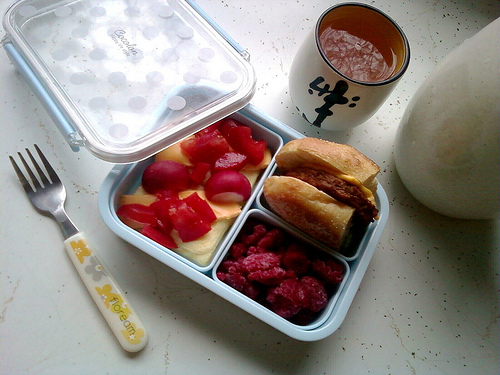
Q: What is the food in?
A: A bento box.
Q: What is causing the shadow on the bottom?
A: Bento box.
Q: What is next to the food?
A: A fork.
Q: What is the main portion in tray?
A: Vegetables.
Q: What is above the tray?
A: Cup of drink.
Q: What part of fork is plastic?
A: Bottom.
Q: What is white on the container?
A: A lid.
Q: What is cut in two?
A: The bread.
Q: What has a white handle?
A: The fork.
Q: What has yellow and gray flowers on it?
A: Fork handle.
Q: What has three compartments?
A: Food container.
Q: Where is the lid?
A: On top of the food container.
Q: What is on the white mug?
A: An asian character.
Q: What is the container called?
A: Bento box.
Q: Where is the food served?
A: Compartment box.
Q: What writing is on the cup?
A: Asian.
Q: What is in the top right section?
A: Sandwich.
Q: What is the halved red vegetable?
A: Radish.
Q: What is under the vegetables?
A: Cheese.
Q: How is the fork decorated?
A: Gray and yellow flowers.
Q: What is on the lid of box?
A: Gray polka dots.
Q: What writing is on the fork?
A: Floream.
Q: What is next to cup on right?
A: Carafe.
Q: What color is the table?
A: White.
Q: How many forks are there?
A: One.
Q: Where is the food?
A: In a tray.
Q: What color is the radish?
A: Red.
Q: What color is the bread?
A: Beige.